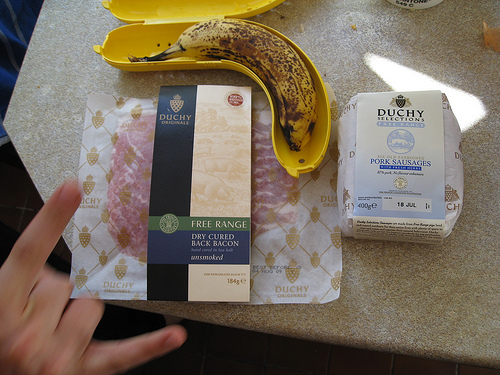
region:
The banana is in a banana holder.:
[136, 12, 325, 153]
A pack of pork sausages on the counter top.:
[328, 88, 463, 228]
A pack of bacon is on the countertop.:
[107, 118, 301, 308]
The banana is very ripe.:
[171, 24, 330, 125]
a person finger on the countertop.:
[24, 188, 129, 296]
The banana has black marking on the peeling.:
[198, 19, 293, 94]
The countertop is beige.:
[302, 165, 498, 325]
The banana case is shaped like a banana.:
[92, 9, 348, 136]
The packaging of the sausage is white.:
[328, 56, 472, 244]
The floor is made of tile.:
[7, 171, 34, 222]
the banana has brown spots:
[277, 67, 324, 117]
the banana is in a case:
[103, 17, 345, 184]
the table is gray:
[377, 260, 469, 315]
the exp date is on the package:
[384, 189, 430, 216]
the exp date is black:
[380, 195, 425, 214]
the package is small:
[330, 78, 469, 245]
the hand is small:
[0, 170, 182, 373]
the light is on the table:
[365, 39, 419, 87]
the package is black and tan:
[158, 91, 251, 170]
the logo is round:
[157, 208, 178, 236]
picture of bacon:
[97, 73, 383, 358]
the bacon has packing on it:
[107, 77, 304, 352]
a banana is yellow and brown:
[109, 41, 451, 201]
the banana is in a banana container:
[114, 21, 419, 216]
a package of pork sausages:
[140, 118, 492, 257]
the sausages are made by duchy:
[347, 93, 499, 292]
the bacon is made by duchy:
[114, 103, 261, 300]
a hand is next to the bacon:
[33, 159, 142, 354]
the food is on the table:
[50, 84, 490, 329]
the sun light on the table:
[371, 41, 493, 152]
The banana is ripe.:
[116, 18, 334, 157]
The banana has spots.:
[119, 12, 333, 171]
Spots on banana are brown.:
[121, 13, 330, 158]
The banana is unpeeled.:
[119, 14, 327, 164]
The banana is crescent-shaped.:
[89, 0, 346, 182]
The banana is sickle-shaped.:
[97, 7, 352, 185]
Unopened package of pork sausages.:
[333, 75, 465, 249]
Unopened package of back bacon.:
[54, 82, 352, 319]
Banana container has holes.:
[76, 3, 318, 180]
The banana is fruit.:
[123, 5, 346, 205]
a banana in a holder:
[84, 3, 441, 185]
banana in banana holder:
[80, 4, 497, 259]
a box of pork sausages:
[312, 40, 496, 259]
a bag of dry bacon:
[57, 45, 466, 374]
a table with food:
[41, 0, 496, 362]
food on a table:
[87, 13, 497, 357]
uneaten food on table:
[54, 16, 499, 288]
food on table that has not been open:
[48, 16, 479, 313]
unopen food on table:
[67, 10, 479, 362]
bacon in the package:
[41, 77, 390, 340]